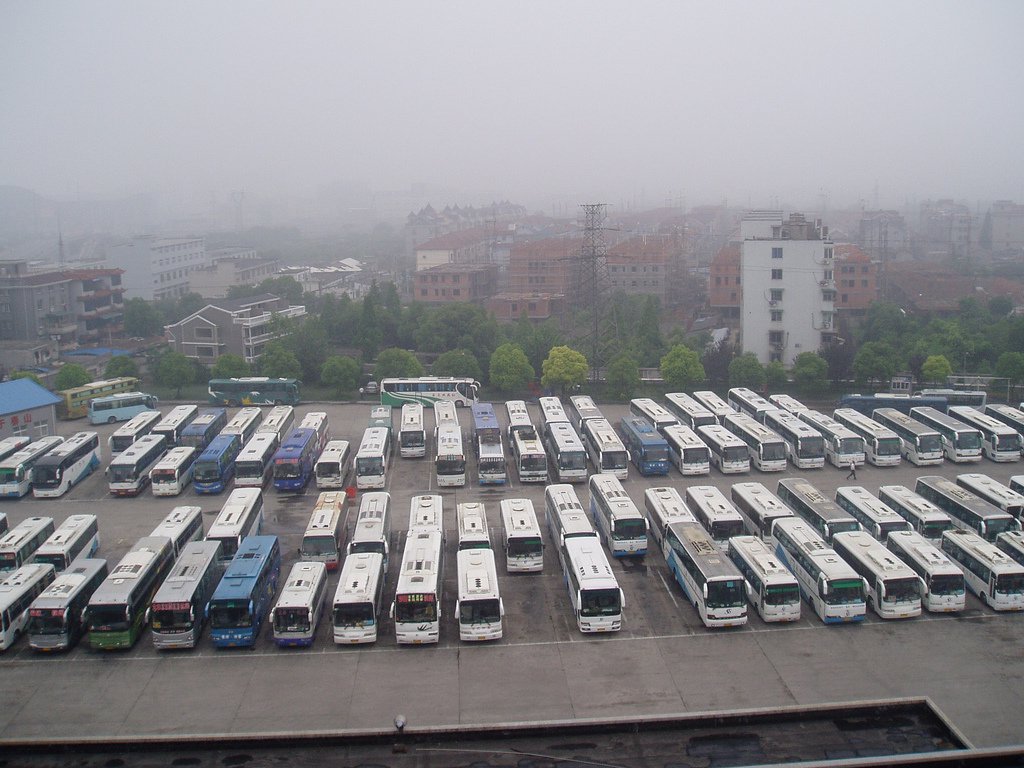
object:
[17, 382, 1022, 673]
buses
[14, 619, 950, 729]
sidewalk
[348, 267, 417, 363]
bush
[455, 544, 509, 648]
bus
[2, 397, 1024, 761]
parking lot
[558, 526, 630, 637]
bus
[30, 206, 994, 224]
grey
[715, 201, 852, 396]
building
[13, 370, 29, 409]
roof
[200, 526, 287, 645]
bus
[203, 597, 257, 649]
front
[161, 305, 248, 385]
building